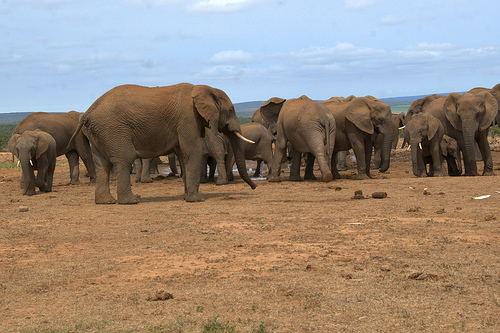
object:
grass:
[0, 136, 499, 332]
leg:
[104, 130, 139, 205]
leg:
[304, 137, 334, 183]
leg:
[134, 154, 143, 183]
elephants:
[423, 90, 496, 176]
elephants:
[320, 99, 395, 180]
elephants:
[201, 121, 278, 181]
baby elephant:
[5, 128, 57, 196]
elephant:
[401, 111, 462, 179]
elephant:
[11, 110, 86, 186]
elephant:
[132, 152, 183, 183]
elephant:
[258, 95, 336, 183]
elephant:
[465, 84, 498, 162]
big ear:
[189, 84, 221, 135]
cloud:
[0, 0, 499, 115]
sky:
[0, 0, 499, 115]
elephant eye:
[229, 108, 234, 111]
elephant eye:
[29, 147, 33, 151]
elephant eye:
[17, 148, 19, 152]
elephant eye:
[419, 128, 426, 134]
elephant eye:
[454, 112, 459, 117]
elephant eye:
[477, 111, 480, 117]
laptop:
[63, 74, 489, 214]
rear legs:
[258, 137, 275, 180]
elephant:
[389, 113, 405, 150]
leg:
[139, 158, 154, 182]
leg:
[91, 144, 118, 204]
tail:
[59, 123, 84, 154]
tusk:
[231, 131, 256, 145]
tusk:
[395, 124, 408, 132]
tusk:
[27, 159, 34, 168]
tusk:
[14, 160, 20, 168]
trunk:
[229, 118, 258, 191]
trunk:
[459, 119, 478, 175]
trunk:
[408, 138, 423, 176]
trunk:
[378, 130, 392, 174]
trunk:
[18, 149, 31, 195]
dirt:
[0, 137, 498, 333]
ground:
[0, 89, 498, 333]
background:
[0, 0, 498, 332]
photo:
[0, 0, 499, 332]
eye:
[226, 111, 235, 120]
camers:
[69, 61, 466, 319]